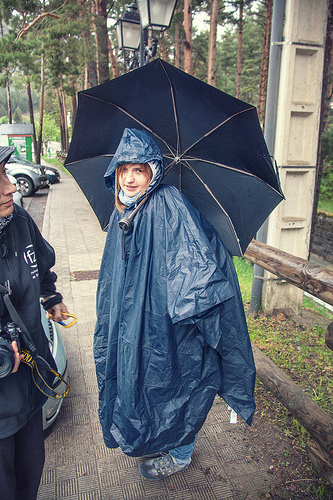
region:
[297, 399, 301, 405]
part of a board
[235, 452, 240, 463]
part of a path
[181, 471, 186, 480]
part of a shoe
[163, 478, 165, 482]
edge of a shoe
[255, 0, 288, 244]
Metal post attached with clips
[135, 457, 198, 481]
Grey and black tennis shoes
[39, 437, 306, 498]
Cement tiled sidewalk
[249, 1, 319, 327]
Cement column with pole attached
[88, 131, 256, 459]
Woman clad in blue slicker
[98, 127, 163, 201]
Blue hood covering woman's head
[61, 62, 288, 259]
Umbrella resting on woman's shoulder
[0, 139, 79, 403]
Man in hat holding camera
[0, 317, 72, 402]
Camera lens and carrying strap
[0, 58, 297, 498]
Two people standing out in rain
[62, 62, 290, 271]
a large black umbrella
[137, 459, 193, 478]
a girl's gray tennis shoe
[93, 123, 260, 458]
a girl's raincoat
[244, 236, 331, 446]
part of a wooden fence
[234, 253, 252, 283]
a section of green grass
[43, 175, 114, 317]
part of a sidewalk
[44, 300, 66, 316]
the hand of a woman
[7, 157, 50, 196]
part of a vehicle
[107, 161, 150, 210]
part of a girl's brown hair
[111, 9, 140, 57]
a black lamp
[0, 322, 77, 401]
a black camera in a persons hand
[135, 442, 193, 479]
a tennis shoe on the ground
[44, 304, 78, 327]
a yellow rope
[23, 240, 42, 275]
white logo on a jacket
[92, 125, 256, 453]
a blue tarp on a girl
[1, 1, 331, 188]
trees outside in the rain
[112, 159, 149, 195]
a girls face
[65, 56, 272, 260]
a blue umbrella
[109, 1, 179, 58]
a square light post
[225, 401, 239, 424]
garbage on the ground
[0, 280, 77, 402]
Man holding a camera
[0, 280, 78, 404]
Man is holding a camera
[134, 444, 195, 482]
Girl wearing shoes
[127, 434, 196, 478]
Girl is wearing shoes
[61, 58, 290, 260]
Girl holding an umbrella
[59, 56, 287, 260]
Girl is holding an umbrella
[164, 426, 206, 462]
Girl wearing blue jeans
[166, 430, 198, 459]
Girl is wearing blue jeans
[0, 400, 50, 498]
Man wearing black pants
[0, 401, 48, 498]
Man is wearing black pants